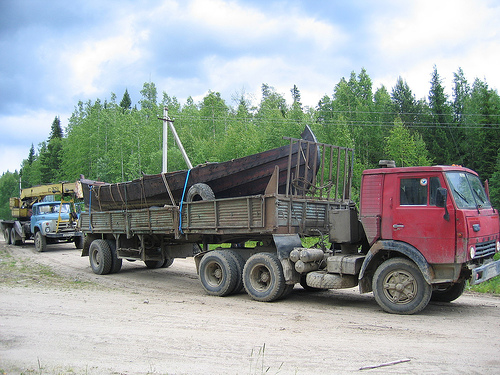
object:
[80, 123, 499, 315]
truck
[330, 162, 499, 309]
cab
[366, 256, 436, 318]
wheel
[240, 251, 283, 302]
wheel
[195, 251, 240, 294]
wheel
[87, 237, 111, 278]
wheel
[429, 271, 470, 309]
wheel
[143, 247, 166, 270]
wheel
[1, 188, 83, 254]
truck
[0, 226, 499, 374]
road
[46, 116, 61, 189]
tree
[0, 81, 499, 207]
forest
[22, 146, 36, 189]
tree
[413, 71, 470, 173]
tree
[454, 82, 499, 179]
tree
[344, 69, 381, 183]
tree